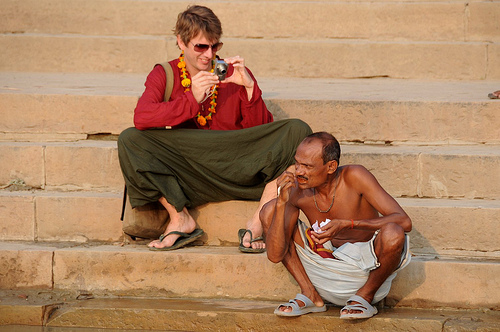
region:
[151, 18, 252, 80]
man with sunglasses on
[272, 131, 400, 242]
man wearing no shirt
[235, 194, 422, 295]
man wearing white shorts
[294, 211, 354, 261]
something white in mans hand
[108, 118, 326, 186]
man wearing olive green pants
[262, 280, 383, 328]
man wearing light blue sandals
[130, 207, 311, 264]
man wearing flip flops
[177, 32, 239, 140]
man wearing something orange around neck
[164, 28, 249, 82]
man using a camera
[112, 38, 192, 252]
man has brown bag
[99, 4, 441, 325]
two people sitting on steps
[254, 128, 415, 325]
man crouching on steps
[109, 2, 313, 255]
man sitting on steps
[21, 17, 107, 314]
concrete steps where people are sitting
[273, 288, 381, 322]
sandals on man's feet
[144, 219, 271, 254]
green flip flops on man's feet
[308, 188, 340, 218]
necklace on a man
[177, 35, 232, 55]
sunglasses on a man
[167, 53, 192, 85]
lei around man's neck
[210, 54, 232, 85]
camera in man's hands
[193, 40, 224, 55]
Glasses on a man's head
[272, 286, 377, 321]
Grey sandals on a man's feet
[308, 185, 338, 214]
Necklace on a man's neck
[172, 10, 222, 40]
Brown hair on a man's head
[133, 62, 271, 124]
Man wearing a maroon shirt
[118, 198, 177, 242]
Brown bag behind a man's foot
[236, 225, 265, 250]
Flip flop on a man's left foot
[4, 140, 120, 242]
Bricks on steps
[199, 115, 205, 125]
Orange shell on a man's necklace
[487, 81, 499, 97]
Toes from a person's foot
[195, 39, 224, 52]
Red tints of sunglasses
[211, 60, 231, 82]
Gray camera being held by man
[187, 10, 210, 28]
Brunette hair of the man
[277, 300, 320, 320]
Right gray sandals of man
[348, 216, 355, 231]
Small red bracelet of the man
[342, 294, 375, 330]
Left gray sandals of the man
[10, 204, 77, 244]
Small part of the tan steps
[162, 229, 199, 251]
Right green slippers of the camera man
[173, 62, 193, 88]
Yellow decorated necklace of the man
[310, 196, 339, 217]
Gray necklace of the man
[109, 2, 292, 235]
man taking picture of other man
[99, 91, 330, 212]
man's pants are green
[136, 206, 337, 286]
man wearing sandals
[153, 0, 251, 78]
man is smiling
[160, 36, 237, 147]
man has yellow necklace on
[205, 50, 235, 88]
the camera is gray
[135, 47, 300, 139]
man's shirt is red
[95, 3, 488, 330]
men are sitting on steps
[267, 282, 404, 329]
man's sandals are gray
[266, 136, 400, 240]
man is not wearing shirt